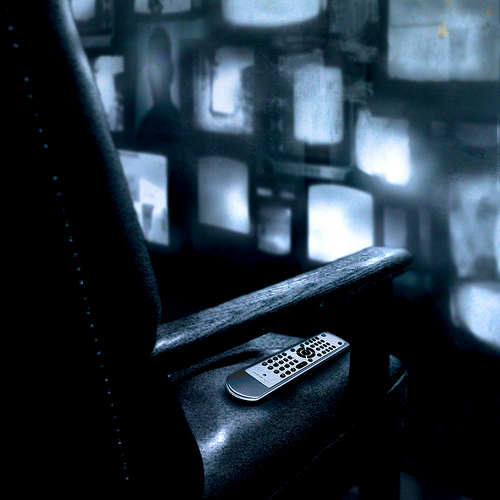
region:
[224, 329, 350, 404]
A black remote with grey top.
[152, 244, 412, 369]
A black arm of a chair.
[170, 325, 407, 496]
A black chair seat.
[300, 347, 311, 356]
Round black circle on a remote.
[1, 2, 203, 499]
Black leather back of a chair.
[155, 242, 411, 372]
A wooden arm on a chair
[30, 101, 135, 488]
Rivets on the seam of a chair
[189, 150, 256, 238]
TV screen on a wall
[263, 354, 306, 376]
Black buttons on a remote control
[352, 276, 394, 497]
Arm support on a chair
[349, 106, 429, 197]
Bright TV screen on a wall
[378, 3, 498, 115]
A large TV on a wall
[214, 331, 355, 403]
The remote on the chair.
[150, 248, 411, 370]
The arm rest of the chair.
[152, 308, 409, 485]
The sitting area of the chair.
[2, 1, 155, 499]
The back of the chair.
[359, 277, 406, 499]
The post of the arm rest.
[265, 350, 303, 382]
The buttons on the bottom of the remote.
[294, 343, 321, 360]
The circle shaped button in the middle of the remote.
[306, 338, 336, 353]
The panel of buttons at the top of the remote.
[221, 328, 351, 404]
remote control with many buttons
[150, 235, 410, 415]
wooden armrest on large and dark chair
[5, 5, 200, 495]
long back cushion of chair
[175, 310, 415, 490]
shiny leather seat cushion on chair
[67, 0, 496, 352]
several blue screens with different images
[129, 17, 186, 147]
head and shoulders showing on one screen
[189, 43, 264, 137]
screen showing on screen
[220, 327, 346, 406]
silver panel on remote control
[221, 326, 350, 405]
flat end opposite curved end on control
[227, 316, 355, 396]
remote control on the chair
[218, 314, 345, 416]
remote control on the chair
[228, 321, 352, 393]
remote control on the chair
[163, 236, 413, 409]
wooden arm on the chair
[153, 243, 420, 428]
wooden arm on the chair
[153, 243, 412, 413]
wooden arm on the chair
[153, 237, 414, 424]
wooden arm on the chair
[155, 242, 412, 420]
wooden arm on the chair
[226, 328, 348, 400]
remote control sitting on a chair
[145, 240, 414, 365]
wooden arm of a computer chair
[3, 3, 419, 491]
computer chair facing many monitors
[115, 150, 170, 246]
monitor screen in the back ground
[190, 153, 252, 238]
monitor screen in the back ground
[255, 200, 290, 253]
monitor screen in the back ground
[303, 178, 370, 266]
monitor screen in the back ground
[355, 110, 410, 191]
monitor screen in the back ground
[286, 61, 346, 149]
monitor screen in the back ground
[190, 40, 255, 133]
monitor screen in the back ground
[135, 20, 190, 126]
monitor screen in the back ground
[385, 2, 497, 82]
monitor screen in the back ground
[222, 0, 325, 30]
monitor screen in the back ground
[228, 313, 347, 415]
remote on the chair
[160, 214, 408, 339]
armrest on the chair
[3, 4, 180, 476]
back of the chair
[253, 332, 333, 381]
buttons on the remote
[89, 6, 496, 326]
screens in front of the chair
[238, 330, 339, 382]
silver background on the buttons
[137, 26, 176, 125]
outline of a man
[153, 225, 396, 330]
wood grain armrest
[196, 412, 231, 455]
reflection on the chair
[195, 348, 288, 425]
bottom of the remote